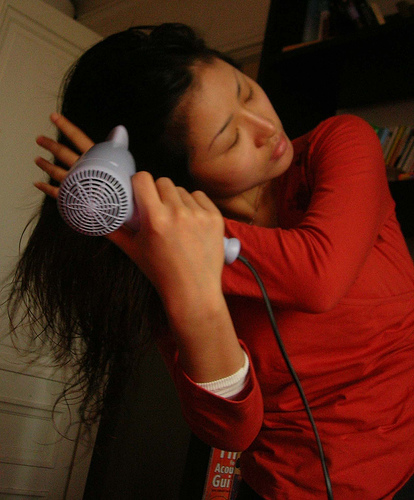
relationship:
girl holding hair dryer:
[30, 34, 409, 327] [34, 132, 233, 268]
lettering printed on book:
[212, 462, 231, 486] [175, 429, 241, 497]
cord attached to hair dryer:
[235, 254, 336, 498] [56, 123, 241, 263]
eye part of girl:
[243, 78, 252, 105] [0, 21, 412, 498]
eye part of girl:
[224, 127, 240, 150] [0, 21, 412, 498]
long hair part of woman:
[0, 24, 188, 460] [30, 18, 409, 494]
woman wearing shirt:
[30, 18, 409, 494] [157, 113, 410, 497]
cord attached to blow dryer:
[234, 252, 344, 498] [58, 125, 241, 266]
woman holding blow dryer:
[30, 18, 409, 494] [54, 126, 136, 232]